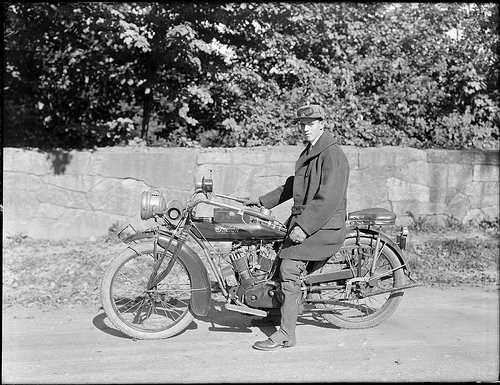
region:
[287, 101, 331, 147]
hat on the man.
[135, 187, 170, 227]
Headlight on the motorcycle.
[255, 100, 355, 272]
coat on the man.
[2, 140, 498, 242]
Stone wall in the background.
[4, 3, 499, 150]
Trees in the background.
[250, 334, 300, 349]
Black shoe on foot.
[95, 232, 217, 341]
Tire on front of the motorcycle.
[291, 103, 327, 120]
Goggles on the hat.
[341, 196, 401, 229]
Seat on the motorcycle.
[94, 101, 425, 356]
man sitting on motorcycle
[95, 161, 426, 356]
vintage cycle with whitewall tire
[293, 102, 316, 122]
safety goggles on man's hat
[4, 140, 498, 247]
low stone wall behind man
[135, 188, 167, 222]
headlight on front of cycle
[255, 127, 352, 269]
men's black over coat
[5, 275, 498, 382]
dirt road in photo foreground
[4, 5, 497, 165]
copse of trees beyond wall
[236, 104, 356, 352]
adult white male on cycle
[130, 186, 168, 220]
a bike has a metal light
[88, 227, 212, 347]
a bike has a round wheel with metal spokes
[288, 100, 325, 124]
a man is wearing a hat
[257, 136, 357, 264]
a man is wearing a coat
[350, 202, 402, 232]
the bike has an extra seat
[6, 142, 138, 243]
a cement wall with cracks on it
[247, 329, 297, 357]
the man is wearing a shoe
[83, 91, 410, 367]
the man is sitting on a bike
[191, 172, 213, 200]
a small horn on a bike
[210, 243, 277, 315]
an engine on a bike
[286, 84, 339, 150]
head of a person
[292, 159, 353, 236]
arm of a person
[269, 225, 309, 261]
hand of a person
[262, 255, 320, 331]
leg of a person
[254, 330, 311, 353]
feet of a person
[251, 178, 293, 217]
arm of a person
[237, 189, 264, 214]
hand of a person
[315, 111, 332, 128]
ear of a person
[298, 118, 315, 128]
eye of a person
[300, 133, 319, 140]
mouth of a person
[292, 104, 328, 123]
Cap on top of man's head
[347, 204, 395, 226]
Flat leather seat on motorcycle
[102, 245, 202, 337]
Front tire of motorcycle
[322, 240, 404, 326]
Rear tire on motorcycle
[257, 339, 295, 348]
Dark boot on man's foot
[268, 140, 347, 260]
Heavy coat on man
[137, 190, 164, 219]
Headlight on front of motorcycle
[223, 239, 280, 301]
Engine of old motorcycle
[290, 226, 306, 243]
Man's hand in lap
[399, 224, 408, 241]
Rear light on motorcycle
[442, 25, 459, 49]
snow on the tree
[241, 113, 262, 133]
snow on the tree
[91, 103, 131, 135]
snow on the tree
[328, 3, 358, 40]
snow on the tree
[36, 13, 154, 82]
snow on the tree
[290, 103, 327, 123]
hat is brown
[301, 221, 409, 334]
the back wheel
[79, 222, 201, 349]
the front wheel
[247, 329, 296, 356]
a brown shoe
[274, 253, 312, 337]
pants are brown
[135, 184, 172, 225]
front light of the bicycle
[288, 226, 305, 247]
hand of the man